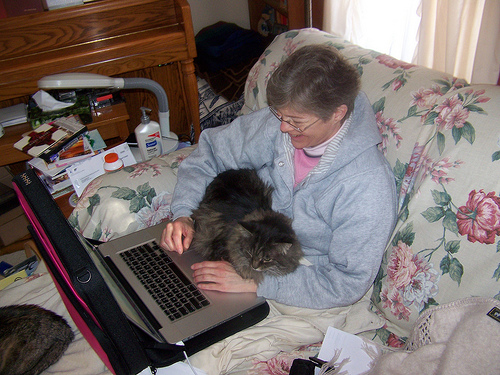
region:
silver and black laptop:
[72, 220, 267, 345]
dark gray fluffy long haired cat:
[185, 165, 300, 275]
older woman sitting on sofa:
[160, 47, 395, 327]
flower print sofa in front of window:
[70, 30, 495, 370]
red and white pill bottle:
[101, 150, 121, 170]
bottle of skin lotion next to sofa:
[132, 101, 159, 156]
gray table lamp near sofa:
[32, 66, 177, 161]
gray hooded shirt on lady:
[170, 92, 395, 303]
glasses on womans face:
[265, 105, 320, 135]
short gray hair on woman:
[265, 40, 358, 121]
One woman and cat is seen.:
[202, 76, 393, 329]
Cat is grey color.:
[195, 170, 281, 297]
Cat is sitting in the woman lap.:
[198, 165, 309, 281]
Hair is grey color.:
[290, 60, 326, 85]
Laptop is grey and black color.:
[115, 235, 200, 331]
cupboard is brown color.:
[37, 18, 183, 48]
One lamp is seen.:
[37, 65, 173, 147]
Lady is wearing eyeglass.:
[268, 106, 319, 146]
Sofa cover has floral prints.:
[392, 123, 487, 233]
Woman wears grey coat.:
[311, 183, 370, 262]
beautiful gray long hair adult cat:
[178, 164, 303, 286]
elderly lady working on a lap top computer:
[73, 71, 405, 342]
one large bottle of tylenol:
[96, 143, 126, 189]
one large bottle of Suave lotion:
[132, 111, 184, 185]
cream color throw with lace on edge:
[366, 288, 481, 371]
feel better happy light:
[0, 57, 179, 169]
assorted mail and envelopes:
[15, 106, 127, 185]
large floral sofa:
[237, 21, 499, 196]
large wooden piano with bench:
[1, 26, 242, 158]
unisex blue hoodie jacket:
[161, 112, 420, 317]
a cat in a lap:
[176, 167, 299, 284]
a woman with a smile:
[256, 42, 358, 155]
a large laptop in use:
[2, 160, 262, 373]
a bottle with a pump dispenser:
[135, 105, 167, 166]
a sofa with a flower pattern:
[71, 35, 497, 371]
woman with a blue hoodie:
[150, 45, 390, 335]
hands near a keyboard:
[114, 214, 261, 324]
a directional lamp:
[28, 62, 175, 158]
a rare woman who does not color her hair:
[252, 39, 373, 164]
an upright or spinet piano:
[0, 32, 208, 177]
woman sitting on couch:
[116, 18, 433, 368]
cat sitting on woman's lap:
[174, 156, 306, 298]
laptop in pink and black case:
[11, 155, 273, 360]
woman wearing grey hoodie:
[181, 54, 404, 327]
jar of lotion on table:
[123, 98, 170, 169]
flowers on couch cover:
[417, 78, 498, 243]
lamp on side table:
[27, 66, 189, 156]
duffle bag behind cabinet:
[196, 12, 266, 112]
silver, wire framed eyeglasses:
[266, 87, 326, 144]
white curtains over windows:
[410, 3, 494, 87]